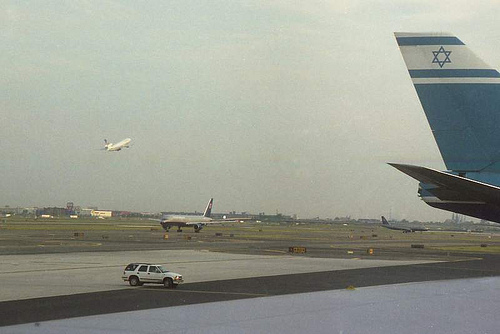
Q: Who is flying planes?
A: Pilots.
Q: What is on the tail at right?
A: A Star of David.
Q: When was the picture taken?
A: During daytime.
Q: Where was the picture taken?
A: At the airport.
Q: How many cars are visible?
A: One.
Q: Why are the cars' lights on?
A: It's getting darker.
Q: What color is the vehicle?
A: White.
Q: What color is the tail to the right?
A: White and blue.